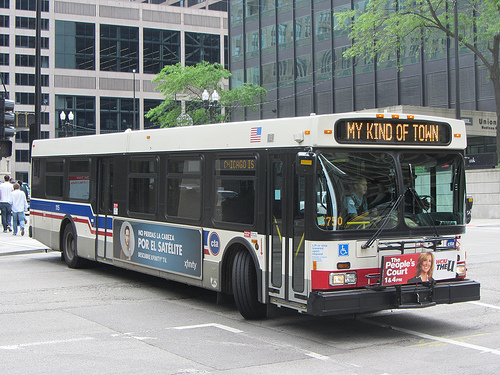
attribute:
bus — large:
[0, 41, 498, 344]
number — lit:
[319, 214, 342, 228]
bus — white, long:
[21, 90, 488, 356]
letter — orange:
[346, 122, 356, 137]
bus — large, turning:
[36, 111, 483, 332]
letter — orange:
[346, 124, 353, 139]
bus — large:
[17, 105, 489, 320]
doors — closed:
[262, 146, 307, 312]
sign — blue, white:
[339, 242, 349, 254]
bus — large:
[21, 87, 488, 325]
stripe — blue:
[26, 197, 111, 232]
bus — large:
[30, 111, 474, 308]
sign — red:
[381, 253, 458, 286]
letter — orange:
[411, 121, 421, 142]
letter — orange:
[346, 122, 441, 140]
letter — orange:
[415, 122, 427, 145]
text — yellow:
[341, 116, 449, 143]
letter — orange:
[377, 123, 386, 141]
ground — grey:
[1, 266, 245, 369]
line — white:
[369, 303, 499, 373]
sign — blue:
[109, 217, 207, 279]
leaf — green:
[165, 65, 171, 70]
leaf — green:
[200, 60, 204, 64]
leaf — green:
[200, 77, 205, 81]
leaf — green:
[427, 55, 430, 61]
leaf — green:
[395, 65, 401, 71]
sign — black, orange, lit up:
[346, 117, 440, 143]